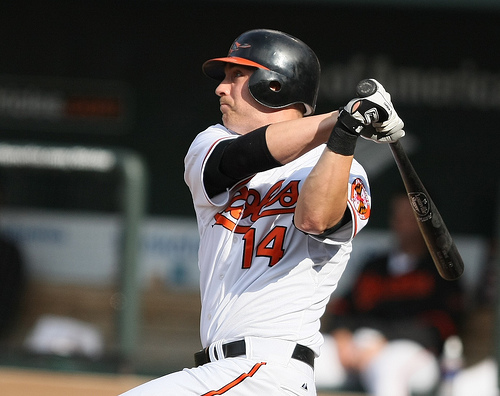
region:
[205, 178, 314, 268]
shadow is cast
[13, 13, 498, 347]
it is baseball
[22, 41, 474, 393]
it is in a baseball field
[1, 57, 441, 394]
the batter is holding a bat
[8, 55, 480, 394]
it is sunny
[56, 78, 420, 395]
the batters top is white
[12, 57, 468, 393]
it is an outdoor scene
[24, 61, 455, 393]
it is a daytime scene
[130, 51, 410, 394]
the bat is black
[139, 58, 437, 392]
the batter is a man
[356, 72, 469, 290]
Black baseball bat with sticker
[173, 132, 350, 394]
White and orange baseball uniform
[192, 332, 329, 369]
Leather black belt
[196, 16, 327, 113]
Black and orange baseball helmet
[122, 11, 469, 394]
Baseball player playing baseball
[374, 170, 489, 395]
Man sitting in the dugout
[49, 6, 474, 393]
Batter after he hits the baseball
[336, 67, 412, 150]
White, gray, and black gloves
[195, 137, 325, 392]
Baseball players uniform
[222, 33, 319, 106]
Black protection helmet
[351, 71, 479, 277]
black baseball bat with white writing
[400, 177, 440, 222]
a logo printed in white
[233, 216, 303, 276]
the number fourteen in orange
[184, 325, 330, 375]
a black leather belt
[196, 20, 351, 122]
a black and orange helmet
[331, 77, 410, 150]
black and white batting gloves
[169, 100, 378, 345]
a white and orange jersey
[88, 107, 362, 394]
a clean baseball uniform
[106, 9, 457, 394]
an athlete in motion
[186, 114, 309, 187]
a soft black arm brace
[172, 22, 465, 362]
a baseball player swinging a bat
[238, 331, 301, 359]
a white belt loop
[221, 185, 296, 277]
team name and number on a shirt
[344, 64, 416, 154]
hands gripping a bat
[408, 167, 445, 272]
a black baseball bat with white printing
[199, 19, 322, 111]
a black and orange batting helmet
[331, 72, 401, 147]
a person with gloves on their hands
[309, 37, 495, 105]
the name of a company printed on a stadium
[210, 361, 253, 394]
an orange stripe on pants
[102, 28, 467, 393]
a batter who has hit the ball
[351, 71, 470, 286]
a black baseball bat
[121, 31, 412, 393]
a batter making a face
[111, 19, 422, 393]
a player for Baltimore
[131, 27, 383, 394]
a player for the Orioles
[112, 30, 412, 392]
a player in a white uniform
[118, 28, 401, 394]
a uniform with orange and black trim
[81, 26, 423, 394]
a batter wearing batting gloves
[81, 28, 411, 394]
a batter with a batting helmet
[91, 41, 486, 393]
a right handed batter at the end of his swing